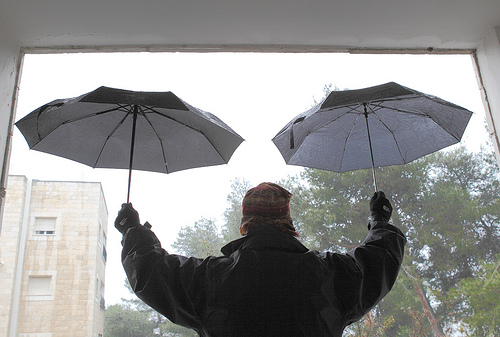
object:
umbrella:
[13, 86, 245, 226]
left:
[1, 9, 43, 337]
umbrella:
[270, 81, 473, 226]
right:
[468, 1, 499, 337]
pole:
[125, 106, 137, 202]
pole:
[362, 105, 378, 192]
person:
[113, 183, 407, 337]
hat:
[239, 182, 300, 236]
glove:
[114, 202, 140, 233]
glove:
[368, 190, 394, 223]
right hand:
[369, 190, 393, 222]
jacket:
[119, 221, 406, 336]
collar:
[221, 233, 310, 257]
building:
[0, 174, 109, 335]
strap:
[289, 116, 306, 150]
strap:
[36, 102, 61, 141]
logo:
[119, 216, 127, 225]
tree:
[105, 302, 153, 337]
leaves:
[471, 279, 497, 304]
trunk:
[415, 284, 447, 336]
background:
[0, 163, 500, 336]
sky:
[7, 51, 494, 303]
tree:
[305, 150, 484, 335]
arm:
[335, 224, 403, 320]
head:
[239, 181, 295, 236]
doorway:
[0, 52, 499, 337]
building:
[1, 1, 499, 335]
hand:
[114, 202, 141, 234]